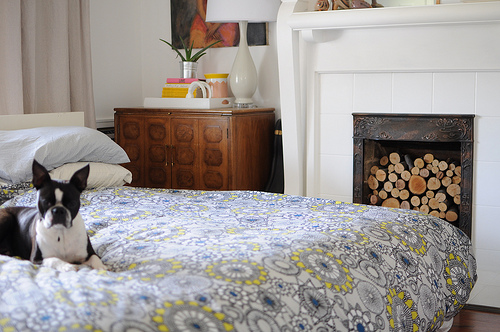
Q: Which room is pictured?
A: It is a bedroom.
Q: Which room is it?
A: It is a bedroom.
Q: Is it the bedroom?
A: Yes, it is the bedroom.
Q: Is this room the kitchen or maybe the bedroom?
A: It is the bedroom.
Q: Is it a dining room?
A: No, it is a bedroom.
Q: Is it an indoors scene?
A: Yes, it is indoors.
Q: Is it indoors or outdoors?
A: It is indoors.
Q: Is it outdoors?
A: No, it is indoors.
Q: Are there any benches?
A: No, there are no benches.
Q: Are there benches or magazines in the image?
A: No, there are no benches or magazines.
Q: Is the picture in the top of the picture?
A: Yes, the picture is in the top of the image.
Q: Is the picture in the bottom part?
A: No, the picture is in the top of the image.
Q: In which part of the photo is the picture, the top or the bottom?
A: The picture is in the top of the image.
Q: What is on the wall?
A: The picture is on the wall.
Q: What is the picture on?
A: The picture is on the wall.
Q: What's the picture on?
A: The picture is on the wall.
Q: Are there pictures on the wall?
A: Yes, there is a picture on the wall.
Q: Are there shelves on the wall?
A: No, there is a picture on the wall.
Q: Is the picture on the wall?
A: Yes, the picture is on the wall.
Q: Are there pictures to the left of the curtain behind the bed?
A: No, the picture is to the right of the curtain.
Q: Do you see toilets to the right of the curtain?
A: No, there is a picture to the right of the curtain.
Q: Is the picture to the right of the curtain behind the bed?
A: Yes, the picture is to the right of the curtain.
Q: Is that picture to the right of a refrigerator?
A: No, the picture is to the right of the curtain.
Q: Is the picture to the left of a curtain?
A: No, the picture is to the right of a curtain.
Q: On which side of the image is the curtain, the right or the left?
A: The curtain is on the left of the image.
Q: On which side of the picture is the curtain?
A: The curtain is on the left of the image.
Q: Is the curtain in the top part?
A: Yes, the curtain is in the top of the image.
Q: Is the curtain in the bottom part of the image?
A: No, the curtain is in the top of the image.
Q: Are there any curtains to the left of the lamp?
A: Yes, there is a curtain to the left of the lamp.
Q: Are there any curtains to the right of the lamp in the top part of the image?
A: No, the curtain is to the left of the lamp.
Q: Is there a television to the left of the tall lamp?
A: No, there is a curtain to the left of the lamp.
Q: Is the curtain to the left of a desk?
A: No, the curtain is to the left of the lamp.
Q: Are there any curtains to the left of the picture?
A: Yes, there is a curtain to the left of the picture.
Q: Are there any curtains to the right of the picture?
A: No, the curtain is to the left of the picture.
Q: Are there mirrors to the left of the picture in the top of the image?
A: No, there is a curtain to the left of the picture.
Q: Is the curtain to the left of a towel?
A: No, the curtain is to the left of the picture.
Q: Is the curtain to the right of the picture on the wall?
A: No, the curtain is to the left of the picture.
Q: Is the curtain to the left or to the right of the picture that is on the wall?
A: The curtain is to the left of the picture.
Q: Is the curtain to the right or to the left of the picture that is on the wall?
A: The curtain is to the left of the picture.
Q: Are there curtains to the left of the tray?
A: Yes, there is a curtain to the left of the tray.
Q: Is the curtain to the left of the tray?
A: Yes, the curtain is to the left of the tray.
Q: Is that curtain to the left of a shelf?
A: No, the curtain is to the left of the tray.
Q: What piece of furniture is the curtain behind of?
A: The curtain is behind the bed.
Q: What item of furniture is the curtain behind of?
A: The curtain is behind the bed.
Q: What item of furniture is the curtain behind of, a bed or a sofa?
A: The curtain is behind a bed.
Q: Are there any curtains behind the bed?
A: Yes, there is a curtain behind the bed.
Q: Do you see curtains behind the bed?
A: Yes, there is a curtain behind the bed.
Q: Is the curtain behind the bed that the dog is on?
A: Yes, the curtain is behind the bed.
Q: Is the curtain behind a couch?
A: No, the curtain is behind the bed.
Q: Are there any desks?
A: No, there are no desks.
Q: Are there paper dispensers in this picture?
A: No, there are no paper dispensers.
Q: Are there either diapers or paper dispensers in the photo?
A: No, there are no paper dispensers or diapers.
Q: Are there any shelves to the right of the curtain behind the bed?
A: No, there is a tray to the right of the curtain.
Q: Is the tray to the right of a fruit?
A: No, the tray is to the right of a curtain.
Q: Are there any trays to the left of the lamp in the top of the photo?
A: Yes, there is a tray to the left of the lamp.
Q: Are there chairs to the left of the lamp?
A: No, there is a tray to the left of the lamp.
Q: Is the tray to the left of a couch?
A: No, the tray is to the left of the lamp.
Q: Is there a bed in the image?
A: Yes, there is a bed.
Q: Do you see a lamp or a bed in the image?
A: Yes, there is a bed.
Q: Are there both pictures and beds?
A: Yes, there are both a bed and a picture.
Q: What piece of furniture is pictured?
A: The piece of furniture is a bed.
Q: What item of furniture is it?
A: The piece of furniture is a bed.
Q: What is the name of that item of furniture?
A: This is a bed.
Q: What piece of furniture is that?
A: This is a bed.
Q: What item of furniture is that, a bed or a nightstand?
A: This is a bed.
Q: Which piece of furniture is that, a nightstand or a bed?
A: This is a bed.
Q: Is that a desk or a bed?
A: That is a bed.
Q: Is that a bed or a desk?
A: That is a bed.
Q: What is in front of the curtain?
A: The bed is in front of the curtain.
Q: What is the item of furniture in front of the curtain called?
A: The piece of furniture is a bed.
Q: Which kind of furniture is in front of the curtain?
A: The piece of furniture is a bed.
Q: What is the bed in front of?
A: The bed is in front of the curtain.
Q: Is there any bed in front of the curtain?
A: Yes, there is a bed in front of the curtain.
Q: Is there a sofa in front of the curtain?
A: No, there is a bed in front of the curtain.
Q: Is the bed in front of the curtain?
A: Yes, the bed is in front of the curtain.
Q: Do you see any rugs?
A: No, there are no rugs.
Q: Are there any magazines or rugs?
A: No, there are no rugs or magazines.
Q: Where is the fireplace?
A: The fireplace is in the bedroom.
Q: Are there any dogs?
A: Yes, there is a dog.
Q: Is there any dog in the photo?
A: Yes, there is a dog.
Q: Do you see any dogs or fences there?
A: Yes, there is a dog.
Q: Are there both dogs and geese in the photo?
A: No, there is a dog but no geese.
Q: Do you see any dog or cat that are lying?
A: Yes, the dog is lying.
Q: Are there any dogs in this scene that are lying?
A: Yes, there is a dog that is lying.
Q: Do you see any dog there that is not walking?
A: Yes, there is a dog that is lying .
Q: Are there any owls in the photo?
A: No, there are no owls.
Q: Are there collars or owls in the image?
A: No, there are no owls or collars.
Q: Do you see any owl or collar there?
A: No, there are no owls or collars.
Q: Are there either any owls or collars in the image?
A: No, there are no owls or collars.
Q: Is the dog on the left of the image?
A: Yes, the dog is on the left of the image.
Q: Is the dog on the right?
A: No, the dog is on the left of the image.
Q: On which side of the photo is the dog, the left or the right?
A: The dog is on the left of the image.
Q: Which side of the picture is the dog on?
A: The dog is on the left of the image.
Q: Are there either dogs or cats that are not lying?
A: No, there is a dog but it is lying.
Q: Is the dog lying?
A: Yes, the dog is lying.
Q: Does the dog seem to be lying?
A: Yes, the dog is lying.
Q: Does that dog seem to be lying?
A: Yes, the dog is lying.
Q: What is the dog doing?
A: The dog is lying.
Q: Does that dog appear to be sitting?
A: No, the dog is lying.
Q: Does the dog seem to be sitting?
A: No, the dog is lying.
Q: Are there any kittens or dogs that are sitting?
A: No, there is a dog but it is lying.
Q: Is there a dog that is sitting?
A: No, there is a dog but it is lying.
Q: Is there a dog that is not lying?
A: No, there is a dog but it is lying.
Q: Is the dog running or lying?
A: The dog is lying.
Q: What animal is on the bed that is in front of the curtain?
A: The animal is a dog.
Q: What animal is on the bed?
A: The animal is a dog.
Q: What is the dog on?
A: The dog is on the bed.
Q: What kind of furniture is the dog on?
A: The dog is on the bed.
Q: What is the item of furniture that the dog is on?
A: The piece of furniture is a bed.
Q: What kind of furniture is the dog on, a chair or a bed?
A: The dog is on a bed.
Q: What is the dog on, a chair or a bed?
A: The dog is on a bed.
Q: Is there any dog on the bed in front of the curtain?
A: Yes, there is a dog on the bed.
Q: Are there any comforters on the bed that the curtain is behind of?
A: No, there is a dog on the bed.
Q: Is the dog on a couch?
A: No, the dog is on the bed.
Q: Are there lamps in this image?
A: Yes, there is a lamp.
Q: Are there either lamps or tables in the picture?
A: Yes, there is a lamp.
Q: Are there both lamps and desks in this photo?
A: No, there is a lamp but no desks.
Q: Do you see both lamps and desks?
A: No, there is a lamp but no desks.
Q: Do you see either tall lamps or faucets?
A: Yes, there is a tall lamp.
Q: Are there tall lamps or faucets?
A: Yes, there is a tall lamp.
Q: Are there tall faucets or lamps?
A: Yes, there is a tall lamp.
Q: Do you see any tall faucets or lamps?
A: Yes, there is a tall lamp.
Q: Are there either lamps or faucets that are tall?
A: Yes, the lamp is tall.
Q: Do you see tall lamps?
A: Yes, there is a tall lamp.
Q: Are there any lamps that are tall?
A: Yes, there is a lamp that is tall.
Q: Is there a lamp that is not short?
A: Yes, there is a tall lamp.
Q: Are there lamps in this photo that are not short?
A: Yes, there is a tall lamp.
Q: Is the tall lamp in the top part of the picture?
A: Yes, the lamp is in the top of the image.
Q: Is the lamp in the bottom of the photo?
A: No, the lamp is in the top of the image.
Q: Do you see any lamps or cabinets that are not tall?
A: No, there is a lamp but it is tall.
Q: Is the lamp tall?
A: Yes, the lamp is tall.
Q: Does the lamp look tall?
A: Yes, the lamp is tall.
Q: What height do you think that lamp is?
A: The lamp is tall.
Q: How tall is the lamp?
A: The lamp is tall.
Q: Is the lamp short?
A: No, the lamp is tall.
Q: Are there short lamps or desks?
A: No, there is a lamp but it is tall.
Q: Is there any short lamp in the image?
A: No, there is a lamp but it is tall.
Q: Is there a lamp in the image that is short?
A: No, there is a lamp but it is tall.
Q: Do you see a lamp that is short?
A: No, there is a lamp but it is tall.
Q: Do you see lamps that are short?
A: No, there is a lamp but it is tall.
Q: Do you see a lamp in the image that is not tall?
A: No, there is a lamp but it is tall.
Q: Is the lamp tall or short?
A: The lamp is tall.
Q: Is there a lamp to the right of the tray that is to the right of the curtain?
A: Yes, there is a lamp to the right of the tray.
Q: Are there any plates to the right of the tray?
A: No, there is a lamp to the right of the tray.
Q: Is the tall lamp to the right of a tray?
A: Yes, the lamp is to the right of a tray.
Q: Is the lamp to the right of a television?
A: No, the lamp is to the right of a tray.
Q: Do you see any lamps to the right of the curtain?
A: Yes, there is a lamp to the right of the curtain.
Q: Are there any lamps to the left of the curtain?
A: No, the lamp is to the right of the curtain.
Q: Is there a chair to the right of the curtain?
A: No, there is a lamp to the right of the curtain.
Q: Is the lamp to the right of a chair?
A: No, the lamp is to the right of the curtain.